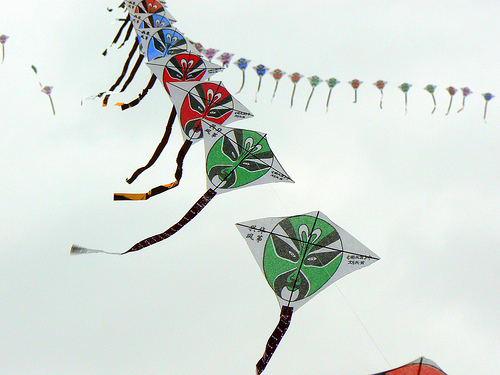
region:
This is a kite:
[221, 198, 391, 373]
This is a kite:
[72, 113, 299, 270]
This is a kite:
[166, 78, 255, 143]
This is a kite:
[141, 54, 223, 94]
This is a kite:
[126, 24, 194, 77]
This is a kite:
[124, 8, 181, 46]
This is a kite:
[215, 37, 235, 89]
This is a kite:
[233, 39, 254, 109]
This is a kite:
[249, 45, 270, 102]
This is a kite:
[266, 58, 283, 107]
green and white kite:
[236, 213, 381, 302]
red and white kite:
[171, 83, 250, 142]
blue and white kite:
[141, 27, 194, 67]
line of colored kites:
[189, 40, 494, 115]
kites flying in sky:
[37, 82, 59, 117]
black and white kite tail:
[63, 188, 215, 258]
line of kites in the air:
[116, 0, 372, 304]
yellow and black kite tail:
[113, 140, 191, 205]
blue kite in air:
[483, 91, 491, 118]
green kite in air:
[325, 77, 337, 102]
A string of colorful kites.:
[100, 0, 491, 360]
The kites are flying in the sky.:
[90, 0, 490, 360]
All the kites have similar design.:
[85, 2, 491, 327]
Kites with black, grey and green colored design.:
[191, 125, 376, 310]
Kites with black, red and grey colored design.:
[145, 51, 236, 136]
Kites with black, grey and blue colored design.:
[130, 10, 185, 50]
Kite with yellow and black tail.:
[105, 174, 184, 205]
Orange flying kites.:
[265, 55, 306, 100]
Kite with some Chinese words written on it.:
[241, 220, 266, 241]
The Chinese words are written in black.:
[203, 117, 224, 142]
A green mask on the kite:
[261, 209, 334, 294]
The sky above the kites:
[12, 182, 65, 361]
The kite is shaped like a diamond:
[238, 198, 377, 318]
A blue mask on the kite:
[186, 79, 231, 131]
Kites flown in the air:
[61, 3, 493, 365]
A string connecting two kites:
[329, 295, 389, 345]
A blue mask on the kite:
[149, 27, 183, 57]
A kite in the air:
[235, 194, 378, 359]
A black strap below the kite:
[251, 303, 300, 371]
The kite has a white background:
[343, 238, 366, 256]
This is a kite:
[191, 116, 295, 217]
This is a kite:
[133, 37, 225, 113]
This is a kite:
[288, 59, 304, 108]